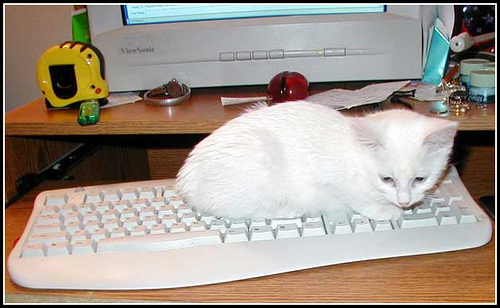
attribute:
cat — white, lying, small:
[220, 110, 408, 212]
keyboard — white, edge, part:
[44, 167, 173, 259]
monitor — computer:
[117, 0, 421, 75]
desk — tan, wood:
[163, 110, 203, 127]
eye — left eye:
[379, 172, 403, 186]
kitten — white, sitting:
[206, 111, 391, 212]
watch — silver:
[72, 100, 94, 127]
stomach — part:
[287, 193, 321, 219]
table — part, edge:
[3, 208, 18, 220]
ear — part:
[346, 123, 398, 148]